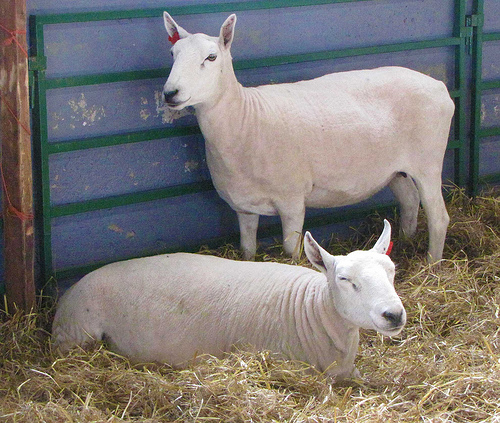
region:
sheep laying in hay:
[35, 243, 475, 383]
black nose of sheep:
[373, 307, 404, 338]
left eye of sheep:
[328, 270, 365, 302]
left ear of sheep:
[303, 233, 335, 280]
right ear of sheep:
[361, 225, 403, 266]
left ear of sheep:
[212, 13, 242, 53]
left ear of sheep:
[146, 5, 188, 43]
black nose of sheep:
[153, 81, 194, 109]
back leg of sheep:
[422, 205, 456, 271]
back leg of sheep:
[386, 178, 419, 243]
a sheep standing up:
[147, 7, 462, 277]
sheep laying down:
[36, 226, 436, 396]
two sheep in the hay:
[45, 13, 466, 397]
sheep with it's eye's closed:
[297, 219, 421, 344]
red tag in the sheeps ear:
[154, 9, 191, 45]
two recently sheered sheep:
[47, 7, 464, 371]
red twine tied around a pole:
[2, 14, 40, 244]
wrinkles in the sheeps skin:
[245, 244, 368, 381]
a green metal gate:
[30, 8, 495, 255]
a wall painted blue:
[29, 7, 486, 262]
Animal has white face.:
[353, 257, 404, 354]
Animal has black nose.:
[381, 292, 413, 371]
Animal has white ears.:
[285, 207, 410, 279]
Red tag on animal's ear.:
[378, 240, 402, 274]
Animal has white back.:
[102, 280, 232, 347]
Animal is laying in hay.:
[118, 227, 339, 419]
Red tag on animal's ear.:
[156, 30, 179, 51]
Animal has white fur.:
[220, 124, 410, 201]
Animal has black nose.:
[162, 87, 207, 115]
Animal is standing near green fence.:
[153, 167, 253, 219]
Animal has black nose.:
[362, 301, 421, 335]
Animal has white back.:
[113, 250, 248, 388]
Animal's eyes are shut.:
[328, 265, 395, 310]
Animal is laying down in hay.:
[87, 238, 347, 420]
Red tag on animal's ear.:
[148, 27, 198, 59]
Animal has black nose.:
[143, 74, 201, 106]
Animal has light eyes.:
[142, 43, 257, 81]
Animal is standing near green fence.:
[111, 44, 455, 221]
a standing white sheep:
[146, 7, 454, 253]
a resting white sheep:
[37, 220, 418, 388]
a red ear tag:
[161, 26, 183, 45]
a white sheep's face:
[153, 11, 243, 116]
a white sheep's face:
[296, 215, 414, 345]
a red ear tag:
[378, 236, 397, 258]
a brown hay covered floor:
[13, 206, 498, 421]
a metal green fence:
[22, 8, 498, 296]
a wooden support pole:
[0, 14, 34, 321]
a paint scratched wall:
[48, 89, 108, 134]